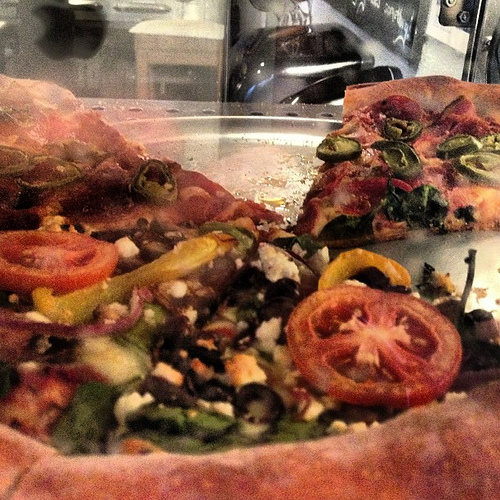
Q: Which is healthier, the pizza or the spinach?
A: The spinach is healthier than the pizza.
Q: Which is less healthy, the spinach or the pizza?
A: The pizza is less healthy than the spinach.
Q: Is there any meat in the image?
A: Yes, there is meat.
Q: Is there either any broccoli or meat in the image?
A: Yes, there is meat.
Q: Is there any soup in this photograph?
A: No, there is no soup.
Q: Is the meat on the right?
A: Yes, the meat is on the right of the image.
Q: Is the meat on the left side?
A: No, the meat is on the right of the image.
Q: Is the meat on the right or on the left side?
A: The meat is on the right of the image.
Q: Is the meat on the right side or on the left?
A: The meat is on the right of the image.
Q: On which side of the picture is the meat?
A: The meat is on the right of the image.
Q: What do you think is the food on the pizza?
A: The food is meat.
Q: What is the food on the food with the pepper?
A: The food is meat.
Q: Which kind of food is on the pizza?
A: The food is meat.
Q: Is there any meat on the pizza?
A: Yes, there is meat on the pizza.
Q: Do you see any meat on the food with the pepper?
A: Yes, there is meat on the pizza.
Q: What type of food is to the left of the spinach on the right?
A: The food is meat.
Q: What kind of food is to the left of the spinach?
A: The food is meat.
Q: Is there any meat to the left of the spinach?
A: Yes, there is meat to the left of the spinach.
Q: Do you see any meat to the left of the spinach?
A: Yes, there is meat to the left of the spinach.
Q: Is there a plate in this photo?
A: Yes, there is a plate.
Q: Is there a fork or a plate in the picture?
A: Yes, there is a plate.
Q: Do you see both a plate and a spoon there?
A: No, there is a plate but no spoons.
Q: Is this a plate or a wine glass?
A: This is a plate.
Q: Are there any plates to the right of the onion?
A: Yes, there is a plate to the right of the onion.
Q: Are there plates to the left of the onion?
A: No, the plate is to the right of the onion.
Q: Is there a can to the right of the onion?
A: No, there is a plate to the right of the onion.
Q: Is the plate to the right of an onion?
A: Yes, the plate is to the right of an onion.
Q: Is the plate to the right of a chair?
A: No, the plate is to the right of an onion.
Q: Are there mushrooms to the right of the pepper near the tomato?
A: No, there is a plate to the right of the pepper.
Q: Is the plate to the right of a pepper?
A: Yes, the plate is to the right of a pepper.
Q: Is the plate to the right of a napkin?
A: No, the plate is to the right of a pepper.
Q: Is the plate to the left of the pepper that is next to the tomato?
A: No, the plate is to the right of the pepper.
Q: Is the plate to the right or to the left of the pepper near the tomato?
A: The plate is to the right of the pepper.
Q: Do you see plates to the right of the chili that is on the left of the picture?
A: Yes, there is a plate to the right of the chili.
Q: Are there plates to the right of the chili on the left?
A: Yes, there is a plate to the right of the chili.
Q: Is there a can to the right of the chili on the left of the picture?
A: No, there is a plate to the right of the chili.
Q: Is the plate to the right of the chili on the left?
A: Yes, the plate is to the right of the chili.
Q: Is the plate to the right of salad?
A: No, the plate is to the right of the chili.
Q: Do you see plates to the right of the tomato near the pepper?
A: Yes, there is a plate to the right of the tomato.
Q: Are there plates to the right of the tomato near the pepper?
A: Yes, there is a plate to the right of the tomato.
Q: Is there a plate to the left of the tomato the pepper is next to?
A: No, the plate is to the right of the tomato.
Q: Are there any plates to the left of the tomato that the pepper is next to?
A: No, the plate is to the right of the tomato.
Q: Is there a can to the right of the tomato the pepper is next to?
A: No, there is a plate to the right of the tomato.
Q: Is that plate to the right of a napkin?
A: No, the plate is to the right of a tomato.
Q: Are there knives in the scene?
A: No, there are no knives.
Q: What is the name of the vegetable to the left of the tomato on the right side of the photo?
A: The vegetable is an olive.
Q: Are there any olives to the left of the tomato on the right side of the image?
A: Yes, there is an olive to the left of the tomato.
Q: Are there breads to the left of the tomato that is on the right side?
A: No, there is an olive to the left of the tomato.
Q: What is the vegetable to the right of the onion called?
A: The vegetable is an olive.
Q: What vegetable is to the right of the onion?
A: The vegetable is an olive.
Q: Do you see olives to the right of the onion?
A: Yes, there is an olive to the right of the onion.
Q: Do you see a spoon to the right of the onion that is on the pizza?
A: No, there is an olive to the right of the onion.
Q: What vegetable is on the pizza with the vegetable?
A: The vegetable is an olive.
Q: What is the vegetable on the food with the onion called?
A: The vegetable is an olive.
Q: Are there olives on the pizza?
A: Yes, there is an olive on the pizza.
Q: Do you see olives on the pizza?
A: Yes, there is an olive on the pizza.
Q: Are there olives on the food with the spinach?
A: Yes, there is an olive on the pizza.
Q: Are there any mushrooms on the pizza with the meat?
A: No, there is an olive on the pizza.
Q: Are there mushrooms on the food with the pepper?
A: No, there is an olive on the pizza.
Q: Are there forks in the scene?
A: No, there are no forks.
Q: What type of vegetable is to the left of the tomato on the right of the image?
A: The vegetable is an olive.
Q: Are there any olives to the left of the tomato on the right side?
A: Yes, there is an olive to the left of the tomato.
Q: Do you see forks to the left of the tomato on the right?
A: No, there is an olive to the left of the tomato.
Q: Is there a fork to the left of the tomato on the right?
A: No, there is an olive to the left of the tomato.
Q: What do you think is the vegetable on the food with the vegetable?
A: The vegetable is an olive.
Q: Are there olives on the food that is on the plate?
A: Yes, there is an olive on the pizza.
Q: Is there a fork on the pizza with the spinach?
A: No, there is an olive on the pizza.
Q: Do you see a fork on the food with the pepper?
A: No, there is an olive on the pizza.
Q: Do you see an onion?
A: Yes, there is an onion.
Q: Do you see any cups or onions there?
A: Yes, there is an onion.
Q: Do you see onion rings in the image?
A: No, there are no onion rings.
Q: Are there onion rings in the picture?
A: No, there are no onion rings.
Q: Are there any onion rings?
A: No, there are no onion rings.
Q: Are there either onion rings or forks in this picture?
A: No, there are no onion rings or forks.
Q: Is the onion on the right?
A: No, the onion is on the left of the image.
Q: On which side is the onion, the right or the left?
A: The onion is on the left of the image.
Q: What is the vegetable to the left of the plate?
A: The vegetable is an onion.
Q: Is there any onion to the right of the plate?
A: No, the onion is to the left of the plate.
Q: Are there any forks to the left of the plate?
A: No, there is an onion to the left of the plate.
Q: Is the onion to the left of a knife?
A: No, the onion is to the left of a plate.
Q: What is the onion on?
A: The onion is on the pizza.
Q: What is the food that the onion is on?
A: The food is a pizza.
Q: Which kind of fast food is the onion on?
A: The onion is on the pizza.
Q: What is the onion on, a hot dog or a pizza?
A: The onion is on a pizza.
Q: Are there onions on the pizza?
A: Yes, there is an onion on the pizza.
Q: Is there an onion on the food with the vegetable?
A: Yes, there is an onion on the pizza.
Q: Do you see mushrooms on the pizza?
A: No, there is an onion on the pizza.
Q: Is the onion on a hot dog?
A: No, the onion is on the pizza.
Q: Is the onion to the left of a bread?
A: No, the onion is to the left of an olive.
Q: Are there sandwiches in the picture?
A: No, there are no sandwiches.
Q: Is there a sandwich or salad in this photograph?
A: No, there are no sandwiches or salad.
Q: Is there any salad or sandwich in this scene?
A: No, there are no sandwiches or salad.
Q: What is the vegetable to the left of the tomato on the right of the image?
A: The vegetable is an olive.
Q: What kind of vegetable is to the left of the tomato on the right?
A: The vegetable is an olive.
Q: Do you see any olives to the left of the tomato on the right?
A: Yes, there is an olive to the left of the tomato.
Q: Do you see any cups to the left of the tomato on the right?
A: No, there is an olive to the left of the tomato.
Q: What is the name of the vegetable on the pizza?
A: The vegetable is an olive.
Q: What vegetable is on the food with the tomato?
A: The vegetable is an olive.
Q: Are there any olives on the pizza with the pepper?
A: Yes, there is an olive on the pizza.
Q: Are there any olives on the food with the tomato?
A: Yes, there is an olive on the pizza.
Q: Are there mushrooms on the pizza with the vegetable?
A: No, there is an olive on the pizza.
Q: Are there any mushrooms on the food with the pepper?
A: No, there is an olive on the pizza.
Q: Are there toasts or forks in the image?
A: No, there are no forks or toasts.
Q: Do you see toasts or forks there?
A: No, there are no forks or toasts.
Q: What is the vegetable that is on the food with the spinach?
A: The vegetable is chili.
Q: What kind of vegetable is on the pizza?
A: The vegetable is chili.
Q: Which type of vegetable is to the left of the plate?
A: The vegetable is chili.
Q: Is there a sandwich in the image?
A: No, there are no sandwiches.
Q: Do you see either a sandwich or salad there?
A: No, there are no sandwiches or salad.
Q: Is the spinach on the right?
A: Yes, the spinach is on the right of the image.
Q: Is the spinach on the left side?
A: No, the spinach is on the right of the image.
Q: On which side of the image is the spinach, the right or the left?
A: The spinach is on the right of the image.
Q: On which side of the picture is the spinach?
A: The spinach is on the right of the image.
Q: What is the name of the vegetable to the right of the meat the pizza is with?
A: The vegetable is spinach.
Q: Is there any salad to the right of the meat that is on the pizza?
A: No, there is spinach to the right of the meat.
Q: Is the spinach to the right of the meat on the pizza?
A: Yes, the spinach is to the right of the meat.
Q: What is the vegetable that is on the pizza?
A: The vegetable is spinach.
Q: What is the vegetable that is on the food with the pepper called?
A: The vegetable is spinach.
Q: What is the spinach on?
A: The spinach is on the pizza.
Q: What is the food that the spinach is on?
A: The food is a pizza.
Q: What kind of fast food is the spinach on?
A: The spinach is on the pizza.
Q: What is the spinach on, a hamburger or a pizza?
A: The spinach is on a pizza.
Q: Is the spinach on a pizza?
A: Yes, the spinach is on a pizza.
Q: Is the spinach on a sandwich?
A: No, the spinach is on a pizza.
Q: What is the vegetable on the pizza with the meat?
A: The vegetable is chili.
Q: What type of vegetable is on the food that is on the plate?
A: The vegetable is chili.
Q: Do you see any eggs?
A: No, there are no eggs.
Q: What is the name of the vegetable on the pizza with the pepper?
A: The vegetable is chili.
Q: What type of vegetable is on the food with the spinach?
A: The vegetable is chili.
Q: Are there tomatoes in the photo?
A: Yes, there is a tomato.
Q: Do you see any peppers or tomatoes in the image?
A: Yes, there is a tomato.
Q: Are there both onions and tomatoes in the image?
A: Yes, there are both a tomato and an onion.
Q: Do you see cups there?
A: No, there are no cups.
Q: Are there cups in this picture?
A: No, there are no cups.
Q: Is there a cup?
A: No, there are no cups.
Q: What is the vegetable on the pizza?
A: The vegetable is a tomato.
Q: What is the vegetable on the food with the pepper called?
A: The vegetable is a tomato.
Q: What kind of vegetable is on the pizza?
A: The vegetable is a tomato.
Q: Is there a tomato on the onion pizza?
A: Yes, there is a tomato on the pizza.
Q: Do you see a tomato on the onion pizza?
A: Yes, there is a tomato on the pizza.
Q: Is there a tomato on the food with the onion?
A: Yes, there is a tomato on the pizza.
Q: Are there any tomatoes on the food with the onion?
A: Yes, there is a tomato on the pizza.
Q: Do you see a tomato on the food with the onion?
A: Yes, there is a tomato on the pizza.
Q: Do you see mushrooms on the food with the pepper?
A: No, there is a tomato on the pizza.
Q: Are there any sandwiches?
A: No, there are no sandwiches.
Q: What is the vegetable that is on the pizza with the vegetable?
A: The vegetable is chili.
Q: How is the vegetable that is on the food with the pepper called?
A: The vegetable is chili.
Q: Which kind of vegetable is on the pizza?
A: The vegetable is chili.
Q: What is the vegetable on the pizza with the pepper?
A: The vegetable is chili.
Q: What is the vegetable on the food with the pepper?
A: The vegetable is chili.